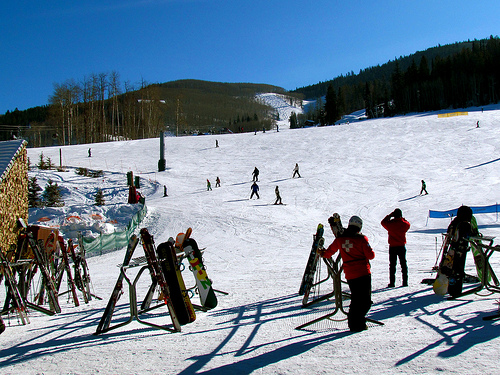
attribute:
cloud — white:
[316, 23, 356, 57]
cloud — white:
[376, 23, 427, 41]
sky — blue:
[1, 1, 496, 121]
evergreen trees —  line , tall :
[265, 31, 498, 119]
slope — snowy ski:
[63, 100, 480, 367]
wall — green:
[74, 203, 154, 265]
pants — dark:
[343, 272, 373, 332]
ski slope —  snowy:
[0, 111, 497, 373]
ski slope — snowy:
[327, 240, 494, 372]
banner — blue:
[426, 203, 498, 230]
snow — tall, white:
[2, 104, 495, 364]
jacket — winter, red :
[379, 216, 414, 246]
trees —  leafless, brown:
[47, 72, 167, 138]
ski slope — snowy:
[239, 107, 499, 234]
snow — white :
[190, 330, 349, 347]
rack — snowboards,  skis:
[91, 228, 230, 338]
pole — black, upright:
[150, 127, 167, 173]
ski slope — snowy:
[153, 104, 499, 373]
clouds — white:
[239, 28, 375, 60]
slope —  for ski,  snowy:
[267, 119, 362, 162]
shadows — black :
[233, 303, 329, 373]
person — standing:
[326, 215, 383, 337]